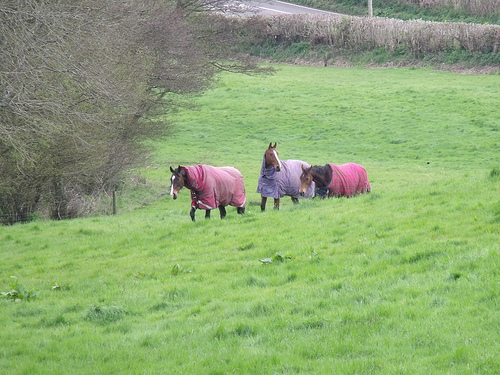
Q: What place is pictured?
A: It is a field.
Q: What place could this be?
A: It is a field.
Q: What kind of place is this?
A: It is a field.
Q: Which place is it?
A: It is a field.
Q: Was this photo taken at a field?
A: Yes, it was taken in a field.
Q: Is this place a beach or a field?
A: It is a field.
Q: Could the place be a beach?
A: No, it is a field.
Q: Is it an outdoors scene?
A: Yes, it is outdoors.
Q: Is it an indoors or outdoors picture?
A: It is outdoors.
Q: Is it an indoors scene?
A: No, it is outdoors.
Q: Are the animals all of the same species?
A: Yes, all the animals are horses.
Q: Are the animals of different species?
A: No, all the animals are horses.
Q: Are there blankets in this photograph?
A: Yes, there is a blanket.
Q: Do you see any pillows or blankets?
A: Yes, there is a blanket.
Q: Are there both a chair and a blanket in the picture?
A: No, there is a blanket but no chairs.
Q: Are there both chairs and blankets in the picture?
A: No, there is a blanket but no chairs.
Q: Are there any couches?
A: No, there are no couches.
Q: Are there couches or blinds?
A: No, there are no couches or blinds.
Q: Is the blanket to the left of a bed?
A: No, the blanket is to the left of a horse.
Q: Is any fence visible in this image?
A: No, there are no fences.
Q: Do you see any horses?
A: Yes, there is a horse.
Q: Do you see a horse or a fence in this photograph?
A: Yes, there is a horse.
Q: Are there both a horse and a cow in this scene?
A: No, there is a horse but no cows.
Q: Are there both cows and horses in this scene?
A: No, there is a horse but no cows.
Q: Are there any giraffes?
A: No, there are no giraffes.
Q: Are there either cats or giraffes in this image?
A: No, there are no giraffes or cats.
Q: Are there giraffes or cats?
A: No, there are no giraffes or cats.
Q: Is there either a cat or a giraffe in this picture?
A: No, there are no giraffes or cats.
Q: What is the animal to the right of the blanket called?
A: The animal is a horse.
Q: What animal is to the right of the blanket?
A: The animal is a horse.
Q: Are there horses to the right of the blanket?
A: Yes, there is a horse to the right of the blanket.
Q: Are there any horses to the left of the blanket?
A: No, the horse is to the right of the blanket.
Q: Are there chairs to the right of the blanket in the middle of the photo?
A: No, there is a horse to the right of the blanket.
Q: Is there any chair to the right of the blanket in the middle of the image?
A: No, there is a horse to the right of the blanket.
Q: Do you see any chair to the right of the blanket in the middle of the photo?
A: No, there is a horse to the right of the blanket.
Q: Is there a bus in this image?
A: No, there are no buses.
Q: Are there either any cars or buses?
A: No, there are no buses or cars.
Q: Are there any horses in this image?
A: Yes, there is a horse.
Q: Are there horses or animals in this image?
A: Yes, there is a horse.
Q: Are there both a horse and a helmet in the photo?
A: No, there is a horse but no helmets.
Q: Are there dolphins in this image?
A: No, there are no dolphins.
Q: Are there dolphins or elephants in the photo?
A: No, there are no dolphins or elephants.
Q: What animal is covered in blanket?
A: The horse is covered in blanket.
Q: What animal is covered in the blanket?
A: The horse is covered in blanket.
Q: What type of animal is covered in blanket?
A: The animal is a horse.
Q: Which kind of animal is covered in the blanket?
A: The animal is a horse.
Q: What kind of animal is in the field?
A: The animal is a horse.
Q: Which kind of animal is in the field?
A: The animal is a horse.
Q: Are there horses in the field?
A: Yes, there is a horse in the field.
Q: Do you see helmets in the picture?
A: No, there are no helmets.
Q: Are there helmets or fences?
A: No, there are no helmets or fences.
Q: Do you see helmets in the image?
A: No, there are no helmets.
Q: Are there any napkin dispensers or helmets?
A: No, there are no helmets or napkin dispensers.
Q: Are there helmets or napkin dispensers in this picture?
A: No, there are no helmets or napkin dispensers.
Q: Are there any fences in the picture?
A: No, there are no fences.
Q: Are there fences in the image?
A: No, there are no fences.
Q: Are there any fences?
A: No, there are no fences.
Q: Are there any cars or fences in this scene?
A: No, there are no fences or cars.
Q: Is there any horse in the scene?
A: Yes, there is a horse.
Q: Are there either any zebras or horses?
A: Yes, there is a horse.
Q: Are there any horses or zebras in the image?
A: Yes, there is a horse.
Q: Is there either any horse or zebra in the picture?
A: Yes, there is a horse.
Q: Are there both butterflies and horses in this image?
A: No, there is a horse but no butterflies.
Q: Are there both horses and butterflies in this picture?
A: No, there is a horse but no butterflies.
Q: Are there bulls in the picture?
A: No, there are no bulls.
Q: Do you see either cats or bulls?
A: No, there are no bulls or cats.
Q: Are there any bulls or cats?
A: No, there are no bulls or cats.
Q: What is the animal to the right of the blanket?
A: The animal is a horse.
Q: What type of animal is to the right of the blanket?
A: The animal is a horse.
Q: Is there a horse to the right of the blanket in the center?
A: Yes, there is a horse to the right of the blanket.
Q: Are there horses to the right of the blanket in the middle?
A: Yes, there is a horse to the right of the blanket.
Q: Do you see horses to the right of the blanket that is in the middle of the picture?
A: Yes, there is a horse to the right of the blanket.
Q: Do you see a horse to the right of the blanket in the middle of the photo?
A: Yes, there is a horse to the right of the blanket.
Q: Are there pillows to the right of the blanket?
A: No, there is a horse to the right of the blanket.